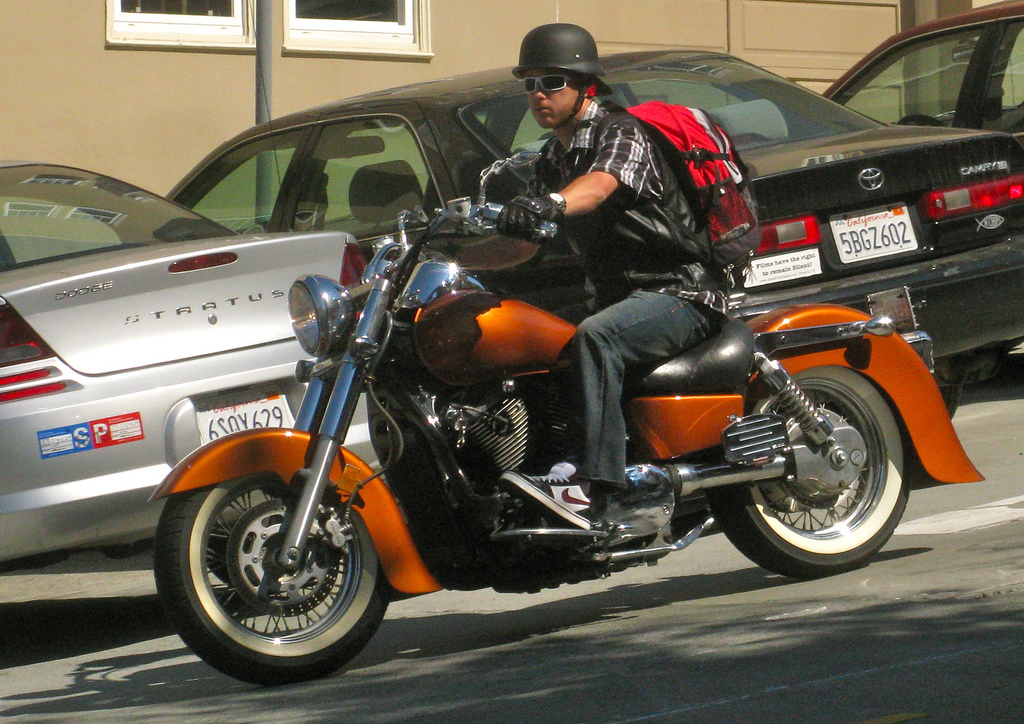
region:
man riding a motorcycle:
[160, 31, 957, 651]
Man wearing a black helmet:
[348, 13, 816, 552]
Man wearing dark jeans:
[407, 23, 759, 573]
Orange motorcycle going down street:
[160, 205, 973, 677]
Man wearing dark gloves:
[397, 15, 806, 604]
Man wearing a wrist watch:
[427, 10, 817, 570]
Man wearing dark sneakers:
[409, 11, 796, 553]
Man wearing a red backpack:
[371, 17, 802, 605]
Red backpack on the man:
[605, 81, 780, 290]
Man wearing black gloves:
[446, 18, 813, 570]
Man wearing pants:
[520, 270, 730, 505]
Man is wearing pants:
[504, 267, 729, 505]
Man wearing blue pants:
[490, 282, 741, 510]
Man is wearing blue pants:
[522, 261, 726, 531]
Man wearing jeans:
[516, 275, 723, 509]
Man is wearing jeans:
[510, 267, 739, 493]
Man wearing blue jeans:
[523, 272, 736, 508]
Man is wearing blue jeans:
[513, 275, 730, 516]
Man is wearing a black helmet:
[509, 23, 630, 128]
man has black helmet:
[484, 22, 587, 79]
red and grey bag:
[583, 79, 805, 247]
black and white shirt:
[485, 125, 790, 247]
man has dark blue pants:
[469, 135, 729, 570]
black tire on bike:
[693, 387, 894, 618]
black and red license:
[191, 381, 341, 483]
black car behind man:
[193, 103, 1012, 401]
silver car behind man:
[3, 172, 452, 515]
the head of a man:
[491, 40, 657, 116]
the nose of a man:
[506, 57, 584, 168]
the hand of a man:
[482, 165, 581, 258]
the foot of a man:
[555, 478, 680, 577]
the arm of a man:
[500, 95, 698, 244]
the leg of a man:
[526, 224, 765, 537]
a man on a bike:
[134, 25, 921, 648]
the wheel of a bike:
[73, 420, 427, 712]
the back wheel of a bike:
[710, 297, 993, 589]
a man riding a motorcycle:
[144, 11, 932, 661]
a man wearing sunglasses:
[525, 60, 577, 98]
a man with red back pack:
[598, 86, 780, 287]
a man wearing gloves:
[497, 194, 570, 236]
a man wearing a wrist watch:
[545, 183, 580, 209]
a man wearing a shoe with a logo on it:
[498, 452, 612, 548]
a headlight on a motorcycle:
[289, 276, 351, 353]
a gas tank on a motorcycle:
[409, 291, 575, 365]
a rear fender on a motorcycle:
[753, 294, 997, 488]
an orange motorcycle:
[179, 230, 971, 660]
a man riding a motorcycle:
[154, 37, 981, 651]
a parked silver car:
[3, 162, 384, 561]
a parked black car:
[230, 75, 995, 357]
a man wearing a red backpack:
[506, 32, 767, 337]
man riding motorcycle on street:
[117, 10, 1022, 720]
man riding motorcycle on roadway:
[125, 7, 1017, 696]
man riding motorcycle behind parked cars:
[45, 6, 995, 721]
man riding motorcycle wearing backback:
[131, 10, 1018, 688]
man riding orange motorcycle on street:
[133, 11, 982, 719]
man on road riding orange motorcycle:
[121, 8, 1014, 677]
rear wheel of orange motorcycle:
[690, 299, 959, 572]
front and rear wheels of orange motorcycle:
[134, 327, 919, 689]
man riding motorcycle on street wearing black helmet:
[119, 10, 990, 694]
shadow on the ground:
[837, 582, 949, 706]